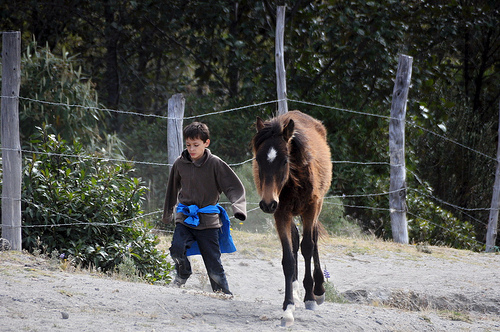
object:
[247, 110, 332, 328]
horse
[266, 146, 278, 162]
spot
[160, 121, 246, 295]
boy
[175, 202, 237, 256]
coat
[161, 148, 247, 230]
hoodie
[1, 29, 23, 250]
stick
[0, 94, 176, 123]
wire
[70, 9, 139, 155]
tree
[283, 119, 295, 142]
ear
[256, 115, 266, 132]
ear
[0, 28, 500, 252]
fence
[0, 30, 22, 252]
post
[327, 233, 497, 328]
field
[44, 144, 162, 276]
bush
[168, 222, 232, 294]
jeans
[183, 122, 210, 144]
hair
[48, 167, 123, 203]
leaves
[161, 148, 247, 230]
shirt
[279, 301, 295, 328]
foot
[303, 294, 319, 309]
foot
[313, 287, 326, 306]
foot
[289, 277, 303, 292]
foot